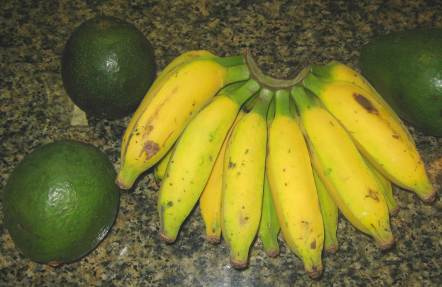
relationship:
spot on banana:
[139, 138, 162, 161] [312, 64, 438, 204]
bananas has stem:
[103, 36, 440, 279] [218, 70, 249, 85]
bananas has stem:
[103, 36, 440, 279] [231, 81, 257, 103]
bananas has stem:
[103, 36, 440, 279] [249, 89, 272, 118]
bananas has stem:
[103, 36, 440, 279] [274, 89, 293, 116]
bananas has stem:
[103, 36, 440, 279] [292, 82, 312, 107]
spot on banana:
[139, 137, 163, 161] [110, 49, 250, 198]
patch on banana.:
[348, 89, 383, 119] [310, 48, 440, 186]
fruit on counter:
[11, 18, 441, 264] [217, 13, 309, 39]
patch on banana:
[348, 89, 383, 119] [303, 74, 433, 202]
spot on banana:
[139, 138, 162, 161] [111, 51, 438, 259]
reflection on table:
[183, 251, 226, 285] [16, 10, 439, 262]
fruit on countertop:
[121, 38, 407, 282] [102, 251, 215, 276]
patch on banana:
[344, 82, 383, 126] [316, 62, 438, 207]